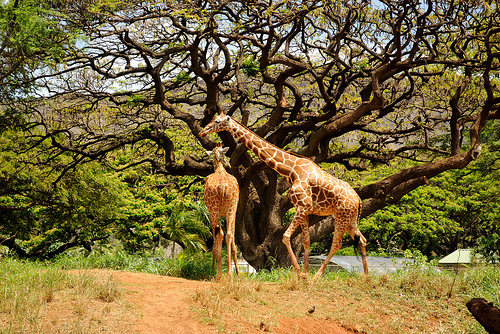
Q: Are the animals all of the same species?
A: Yes, all the animals are giraffes.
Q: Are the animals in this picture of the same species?
A: Yes, all the animals are giraffes.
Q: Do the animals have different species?
A: No, all the animals are giraffes.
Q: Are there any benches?
A: No, there are no benches.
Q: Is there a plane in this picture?
A: No, there are no airplanes.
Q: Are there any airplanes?
A: No, there are no airplanes.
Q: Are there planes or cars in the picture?
A: No, there are no planes or cars.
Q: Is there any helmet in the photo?
A: No, there are no helmets.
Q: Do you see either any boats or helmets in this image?
A: No, there are no helmets or boats.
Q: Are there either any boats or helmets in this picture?
A: No, there are no helmets or boats.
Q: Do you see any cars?
A: No, there are no cars.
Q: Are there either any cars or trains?
A: No, there are no cars or trains.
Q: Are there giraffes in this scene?
A: Yes, there is a giraffe.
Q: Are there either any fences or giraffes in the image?
A: Yes, there is a giraffe.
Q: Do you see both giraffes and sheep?
A: No, there is a giraffe but no sheep.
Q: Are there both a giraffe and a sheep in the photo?
A: No, there is a giraffe but no sheep.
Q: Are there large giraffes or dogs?
A: Yes, there is a large giraffe.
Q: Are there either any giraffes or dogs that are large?
A: Yes, the giraffe is large.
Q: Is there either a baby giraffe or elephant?
A: Yes, there is a baby giraffe.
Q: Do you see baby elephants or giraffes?
A: Yes, there is a baby giraffe.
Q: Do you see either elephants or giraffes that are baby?
A: Yes, the giraffe is a baby.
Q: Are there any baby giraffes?
A: Yes, there is a baby giraffe.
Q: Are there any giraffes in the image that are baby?
A: Yes, there is a giraffe that is a baby.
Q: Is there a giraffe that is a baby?
A: Yes, there is a giraffe that is a baby.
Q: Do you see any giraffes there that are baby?
A: Yes, there is a giraffe that is a baby.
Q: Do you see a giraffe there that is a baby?
A: Yes, there is a giraffe that is a baby.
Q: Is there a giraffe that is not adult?
A: Yes, there is an baby giraffe.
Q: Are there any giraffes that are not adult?
A: Yes, there is an baby giraffe.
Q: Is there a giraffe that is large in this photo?
A: Yes, there is a large giraffe.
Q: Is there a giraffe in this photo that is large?
A: Yes, there is a giraffe that is large.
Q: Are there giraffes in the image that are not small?
A: Yes, there is a large giraffe.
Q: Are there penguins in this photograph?
A: No, there are no penguins.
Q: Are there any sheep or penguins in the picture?
A: No, there are no penguins or sheep.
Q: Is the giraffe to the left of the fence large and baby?
A: Yes, the giraffe is large and baby.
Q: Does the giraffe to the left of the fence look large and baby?
A: Yes, the giraffe is large and baby.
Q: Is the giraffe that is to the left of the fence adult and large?
A: No, the giraffe is large but baby.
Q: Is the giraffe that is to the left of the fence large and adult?
A: No, the giraffe is large but baby.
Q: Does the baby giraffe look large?
A: Yes, the giraffe is large.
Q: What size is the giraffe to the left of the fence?
A: The giraffe is large.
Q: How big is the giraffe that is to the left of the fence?
A: The giraffe is large.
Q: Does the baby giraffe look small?
A: No, the giraffe is large.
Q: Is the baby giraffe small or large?
A: The giraffe is large.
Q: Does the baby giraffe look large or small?
A: The giraffe is large.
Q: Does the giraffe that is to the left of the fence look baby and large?
A: Yes, the giraffe is a baby and large.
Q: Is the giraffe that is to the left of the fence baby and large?
A: Yes, the giraffe is a baby and large.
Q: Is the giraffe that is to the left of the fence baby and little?
A: No, the giraffe is a baby but large.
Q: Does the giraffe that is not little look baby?
A: Yes, the giraffe is a baby.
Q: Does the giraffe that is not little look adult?
A: No, the giraffe is a baby.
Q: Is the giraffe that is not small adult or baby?
A: The giraffe is a baby.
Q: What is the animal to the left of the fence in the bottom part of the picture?
A: The animal is a giraffe.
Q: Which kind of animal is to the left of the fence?
A: The animal is a giraffe.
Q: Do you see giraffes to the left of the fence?
A: Yes, there is a giraffe to the left of the fence.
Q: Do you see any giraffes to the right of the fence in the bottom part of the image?
A: No, the giraffe is to the left of the fence.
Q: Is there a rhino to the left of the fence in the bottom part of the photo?
A: No, there is a giraffe to the left of the fence.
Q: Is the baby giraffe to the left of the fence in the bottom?
A: Yes, the giraffe is to the left of the fence.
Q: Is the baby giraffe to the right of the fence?
A: No, the giraffe is to the left of the fence.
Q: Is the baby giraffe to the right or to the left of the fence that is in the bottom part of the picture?
A: The giraffe is to the left of the fence.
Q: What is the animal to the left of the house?
A: The animal is a giraffe.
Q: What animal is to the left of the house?
A: The animal is a giraffe.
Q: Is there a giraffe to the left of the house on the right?
A: Yes, there is a giraffe to the left of the house.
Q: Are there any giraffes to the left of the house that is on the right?
A: Yes, there is a giraffe to the left of the house.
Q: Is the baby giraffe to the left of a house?
A: Yes, the giraffe is to the left of a house.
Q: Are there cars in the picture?
A: No, there are no cars.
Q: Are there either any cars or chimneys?
A: No, there are no cars or chimneys.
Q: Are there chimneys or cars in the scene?
A: No, there are no cars or chimneys.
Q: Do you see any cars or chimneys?
A: No, there are no cars or chimneys.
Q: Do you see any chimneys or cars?
A: No, there are no cars or chimneys.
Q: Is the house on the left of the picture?
A: No, the house is on the right of the image.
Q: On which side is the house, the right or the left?
A: The house is on the right of the image.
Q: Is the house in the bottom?
A: Yes, the house is in the bottom of the image.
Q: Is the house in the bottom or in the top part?
A: The house is in the bottom of the image.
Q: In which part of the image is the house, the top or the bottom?
A: The house is in the bottom of the image.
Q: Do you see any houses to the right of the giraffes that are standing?
A: Yes, there is a house to the right of the giraffes.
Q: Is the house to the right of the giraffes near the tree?
A: Yes, the house is to the right of the giraffes.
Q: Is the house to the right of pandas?
A: No, the house is to the right of the giraffes.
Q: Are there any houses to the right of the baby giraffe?
A: Yes, there is a house to the right of the giraffe.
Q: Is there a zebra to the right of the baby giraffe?
A: No, there is a house to the right of the giraffe.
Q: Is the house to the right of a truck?
A: No, the house is to the right of the giraffe.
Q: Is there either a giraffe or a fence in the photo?
A: Yes, there are giraffes.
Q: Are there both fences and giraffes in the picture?
A: Yes, there are both giraffes and a fence.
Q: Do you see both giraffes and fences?
A: Yes, there are both giraffes and a fence.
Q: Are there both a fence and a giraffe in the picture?
A: Yes, there are both a giraffe and a fence.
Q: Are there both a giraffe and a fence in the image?
A: Yes, there are both a giraffe and a fence.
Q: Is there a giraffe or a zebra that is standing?
A: Yes, the giraffes are standing.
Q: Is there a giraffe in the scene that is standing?
A: Yes, there are giraffes that are standing.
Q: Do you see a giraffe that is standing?
A: Yes, there are giraffes that are standing.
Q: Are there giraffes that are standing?
A: Yes, there are giraffes that are standing.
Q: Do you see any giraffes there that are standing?
A: Yes, there are giraffes that are standing.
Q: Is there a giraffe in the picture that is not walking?
A: Yes, there are giraffes that are standing.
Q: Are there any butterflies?
A: No, there are no butterflies.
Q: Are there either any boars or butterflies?
A: No, there are no butterflies or boars.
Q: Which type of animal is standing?
A: The animal is giraffes.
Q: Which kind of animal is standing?
A: The animal is giraffes.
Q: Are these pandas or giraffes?
A: These are giraffes.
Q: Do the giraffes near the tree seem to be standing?
A: Yes, the giraffes are standing.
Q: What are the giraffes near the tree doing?
A: The giraffes are standing.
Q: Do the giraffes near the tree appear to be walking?
A: No, the giraffes are standing.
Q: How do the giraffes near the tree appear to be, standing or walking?
A: The giraffes are standing.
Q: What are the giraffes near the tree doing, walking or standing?
A: The giraffes are standing.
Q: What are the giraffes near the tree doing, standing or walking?
A: The giraffes are standing.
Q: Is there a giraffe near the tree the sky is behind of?
A: Yes, there are giraffes near the tree.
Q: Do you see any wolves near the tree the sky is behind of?
A: No, there are giraffes near the tree.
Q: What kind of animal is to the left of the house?
A: The animals are giraffes.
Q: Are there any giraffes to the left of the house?
A: Yes, there are giraffes to the left of the house.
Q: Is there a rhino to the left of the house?
A: No, there are giraffes to the left of the house.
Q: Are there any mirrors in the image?
A: No, there are no mirrors.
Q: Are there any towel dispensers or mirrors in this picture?
A: No, there are no mirrors or towel dispensers.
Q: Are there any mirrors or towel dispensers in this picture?
A: No, there are no mirrors or towel dispensers.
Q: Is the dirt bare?
A: Yes, the dirt is bare.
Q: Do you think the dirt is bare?
A: Yes, the dirt is bare.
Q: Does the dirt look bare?
A: Yes, the dirt is bare.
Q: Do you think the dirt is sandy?
A: No, the dirt is bare.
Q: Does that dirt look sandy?
A: No, the dirt is bare.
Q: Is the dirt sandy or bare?
A: The dirt is bare.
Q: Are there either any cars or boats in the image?
A: No, there are no cars or boats.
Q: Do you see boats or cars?
A: No, there are no cars or boats.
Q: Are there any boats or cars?
A: No, there are no cars or boats.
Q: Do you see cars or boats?
A: No, there are no cars or boats.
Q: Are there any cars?
A: No, there are no cars.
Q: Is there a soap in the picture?
A: No, there are no soaps.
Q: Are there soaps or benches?
A: No, there are no soaps or benches.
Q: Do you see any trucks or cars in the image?
A: No, there are no cars or trucks.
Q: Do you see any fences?
A: Yes, there is a fence.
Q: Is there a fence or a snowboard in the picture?
A: Yes, there is a fence.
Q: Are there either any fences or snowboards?
A: Yes, there is a fence.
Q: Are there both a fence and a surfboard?
A: No, there is a fence but no surfboards.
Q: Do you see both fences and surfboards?
A: No, there is a fence but no surfboards.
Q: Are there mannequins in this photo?
A: No, there are no mannequins.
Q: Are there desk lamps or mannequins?
A: No, there are no mannequins or desk lamps.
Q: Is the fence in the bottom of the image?
A: Yes, the fence is in the bottom of the image.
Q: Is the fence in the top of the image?
A: No, the fence is in the bottom of the image.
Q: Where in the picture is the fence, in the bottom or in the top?
A: The fence is in the bottom of the image.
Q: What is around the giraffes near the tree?
A: The fence is around the giraffes.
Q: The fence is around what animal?
A: The fence is around the giraffes.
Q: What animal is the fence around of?
A: The fence is around the giraffes.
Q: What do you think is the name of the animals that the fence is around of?
A: The animals are giraffes.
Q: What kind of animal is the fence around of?
A: The fence is around the giraffes.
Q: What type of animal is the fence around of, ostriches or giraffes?
A: The fence is around giraffes.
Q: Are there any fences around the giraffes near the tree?
A: Yes, there is a fence around the giraffes.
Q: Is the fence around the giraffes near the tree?
A: Yes, the fence is around the giraffes.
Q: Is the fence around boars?
A: No, the fence is around the giraffes.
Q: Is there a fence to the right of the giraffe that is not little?
A: Yes, there is a fence to the right of the giraffe.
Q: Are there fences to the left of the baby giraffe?
A: No, the fence is to the right of the giraffe.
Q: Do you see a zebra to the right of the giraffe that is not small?
A: No, there is a fence to the right of the giraffe.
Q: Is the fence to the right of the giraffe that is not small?
A: Yes, the fence is to the right of the giraffe.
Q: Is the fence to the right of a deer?
A: No, the fence is to the right of the giraffe.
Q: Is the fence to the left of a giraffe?
A: No, the fence is to the right of a giraffe.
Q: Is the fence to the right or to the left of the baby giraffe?
A: The fence is to the right of the giraffe.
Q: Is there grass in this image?
A: Yes, there is grass.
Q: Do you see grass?
A: Yes, there is grass.